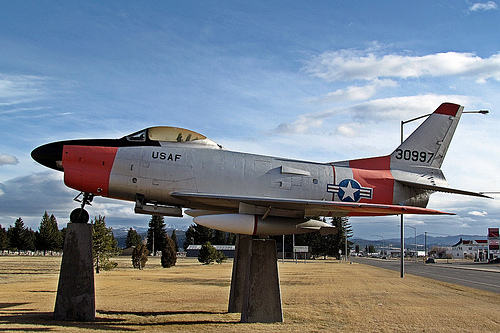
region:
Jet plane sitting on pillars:
[28, 102, 465, 300]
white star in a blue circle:
[337, 179, 356, 204]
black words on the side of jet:
[144, 147, 185, 166]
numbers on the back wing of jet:
[394, 99, 459, 169]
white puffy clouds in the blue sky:
[230, 57, 497, 102]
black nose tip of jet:
[27, 135, 62, 170]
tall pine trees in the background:
[5, 209, 60, 258]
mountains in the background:
[403, 231, 476, 248]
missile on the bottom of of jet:
[191, 206, 337, 242]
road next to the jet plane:
[364, 252, 499, 302]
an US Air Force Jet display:
[31, 101, 493, 236]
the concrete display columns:
[52, 221, 96, 324]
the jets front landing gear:
[68, 189, 93, 226]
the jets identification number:
[395, 147, 435, 166]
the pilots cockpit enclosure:
[119, 125, 216, 147]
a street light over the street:
[464, 108, 493, 115]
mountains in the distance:
[346, 230, 485, 250]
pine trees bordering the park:
[0, 210, 62, 250]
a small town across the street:
[350, 226, 497, 262]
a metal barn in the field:
[185, 242, 233, 259]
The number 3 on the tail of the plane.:
[394, 147, 405, 162]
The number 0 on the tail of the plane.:
[403, 147, 415, 164]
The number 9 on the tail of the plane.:
[411, 148, 421, 161]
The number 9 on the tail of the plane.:
[419, 147, 428, 166]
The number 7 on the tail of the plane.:
[424, 148, 433, 166]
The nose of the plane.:
[32, 145, 67, 177]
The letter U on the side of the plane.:
[150, 148, 160, 161]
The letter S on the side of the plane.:
[158, 148, 168, 162]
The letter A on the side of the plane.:
[164, 151, 176, 166]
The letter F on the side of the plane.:
[172, 150, 185, 165]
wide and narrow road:
[349, 245, 499, 331]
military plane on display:
[30, 100, 472, 236]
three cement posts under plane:
[50, 216, 294, 326]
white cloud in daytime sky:
[380, 45, 470, 87]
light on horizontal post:
[468, 101, 494, 121]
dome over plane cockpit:
[139, 121, 201, 151]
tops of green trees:
[11, 207, 61, 231]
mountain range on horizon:
[410, 227, 467, 248]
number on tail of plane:
[386, 145, 438, 166]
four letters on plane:
[145, 148, 191, 165]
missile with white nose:
[183, 208, 343, 240]